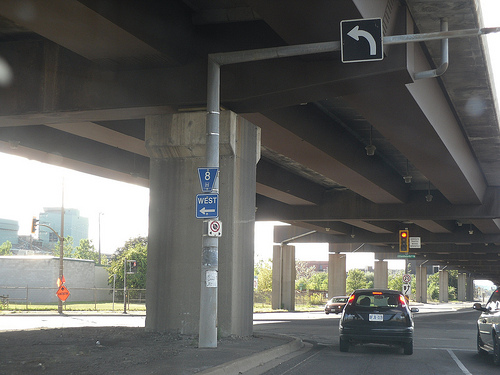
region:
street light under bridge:
[391, 220, 416, 258]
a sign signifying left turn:
[336, 17, 388, 66]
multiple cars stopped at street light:
[318, 286, 498, 366]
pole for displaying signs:
[199, 22, 497, 350]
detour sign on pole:
[56, 273, 74, 305]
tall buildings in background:
[1, 203, 96, 253]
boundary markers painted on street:
[416, 345, 483, 373]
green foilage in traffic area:
[0, 237, 466, 305]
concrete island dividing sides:
[1, 321, 309, 373]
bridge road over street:
[0, 0, 497, 291]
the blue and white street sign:
[197, 163, 217, 191]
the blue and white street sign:
[195, 194, 217, 216]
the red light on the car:
[346, 292, 355, 304]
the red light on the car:
[370, 291, 382, 297]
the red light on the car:
[398, 293, 406, 306]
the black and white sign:
[402, 283, 409, 296]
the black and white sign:
[339, 18, 382, 65]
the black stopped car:
[337, 288, 414, 352]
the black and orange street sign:
[55, 285, 69, 305]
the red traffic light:
[400, 233, 405, 238]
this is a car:
[350, 308, 386, 368]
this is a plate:
[365, 317, 390, 318]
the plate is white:
[373, 302, 387, 336]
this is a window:
[335, 285, 375, 327]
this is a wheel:
[330, 345, 363, 373]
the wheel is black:
[331, 329, 351, 363]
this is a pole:
[172, 253, 230, 351]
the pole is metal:
[137, 252, 269, 319]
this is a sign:
[177, 177, 237, 217]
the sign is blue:
[188, 236, 243, 310]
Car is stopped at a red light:
[321, 217, 428, 362]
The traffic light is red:
[396, 223, 411, 259]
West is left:
[193, 192, 220, 222]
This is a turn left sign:
[337, 18, 386, 68]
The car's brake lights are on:
[333, 285, 420, 361]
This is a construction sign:
[51, 274, 76, 308]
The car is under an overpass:
[3, 0, 450, 360]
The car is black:
[335, 282, 418, 361]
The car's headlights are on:
[321, 292, 352, 317]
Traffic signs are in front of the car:
[399, 268, 416, 311]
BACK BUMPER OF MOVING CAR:
[343, 322, 419, 337]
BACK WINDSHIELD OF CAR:
[351, 290, 407, 306]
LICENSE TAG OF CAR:
[360, 312, 387, 323]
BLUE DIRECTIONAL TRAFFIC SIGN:
[191, 192, 225, 221]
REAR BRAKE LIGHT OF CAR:
[348, 292, 356, 304]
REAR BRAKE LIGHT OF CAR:
[368, 290, 385, 297]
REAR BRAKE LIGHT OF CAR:
[397, 294, 407, 305]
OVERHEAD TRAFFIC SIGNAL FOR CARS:
[393, 225, 410, 256]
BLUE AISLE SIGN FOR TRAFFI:
[197, 165, 221, 192]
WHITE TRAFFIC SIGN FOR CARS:
[204, 217, 226, 242]